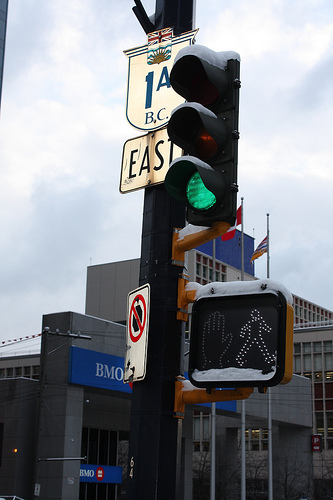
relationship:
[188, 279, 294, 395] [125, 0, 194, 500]
cross sign on light post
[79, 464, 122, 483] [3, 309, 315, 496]
blue sign for a bank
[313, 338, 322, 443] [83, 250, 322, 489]
windows on a building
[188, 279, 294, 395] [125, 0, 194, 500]
cross sign on a light post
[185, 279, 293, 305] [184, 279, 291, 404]
snow on a sign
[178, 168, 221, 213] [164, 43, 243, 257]
light on sign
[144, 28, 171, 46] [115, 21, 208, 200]
flag on sign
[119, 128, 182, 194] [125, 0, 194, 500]
direction sign on light post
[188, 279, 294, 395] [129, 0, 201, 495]
cross sign on pole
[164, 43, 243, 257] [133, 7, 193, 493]
sign on pole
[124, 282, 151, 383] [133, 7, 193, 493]
sign on pole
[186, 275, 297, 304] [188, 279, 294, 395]
snow on cross sign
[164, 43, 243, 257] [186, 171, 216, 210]
sign with light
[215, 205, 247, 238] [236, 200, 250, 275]
flag on pole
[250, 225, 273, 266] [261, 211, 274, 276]
flag on pole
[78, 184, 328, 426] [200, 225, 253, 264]
building with accent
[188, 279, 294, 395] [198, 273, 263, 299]
cross sign with snow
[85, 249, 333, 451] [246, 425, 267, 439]
building with lights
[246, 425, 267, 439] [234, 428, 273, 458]
lights visible through windows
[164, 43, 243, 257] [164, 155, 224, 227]
sign showing light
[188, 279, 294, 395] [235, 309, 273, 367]
cross sign showing a image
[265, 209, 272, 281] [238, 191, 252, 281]
pole on a pole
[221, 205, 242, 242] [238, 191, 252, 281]
flag on a pole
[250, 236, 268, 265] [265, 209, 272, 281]
flag on a pole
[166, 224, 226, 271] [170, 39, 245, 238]
arm of traffic light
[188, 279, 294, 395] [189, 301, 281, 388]
cross sign on cross sign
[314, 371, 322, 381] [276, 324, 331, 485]
window on building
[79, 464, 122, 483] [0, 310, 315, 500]
blue sign on bank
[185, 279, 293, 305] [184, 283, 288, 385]
snow on bottom of sign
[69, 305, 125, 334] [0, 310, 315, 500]
snow on bank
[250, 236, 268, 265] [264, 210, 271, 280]
flag flying on pole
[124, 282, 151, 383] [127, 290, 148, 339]
sign with a cross out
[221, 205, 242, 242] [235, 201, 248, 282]
flag flying on pole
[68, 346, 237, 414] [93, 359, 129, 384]
business sign with letters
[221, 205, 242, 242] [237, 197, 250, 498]
flag on pole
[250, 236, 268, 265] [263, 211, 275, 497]
flag on pole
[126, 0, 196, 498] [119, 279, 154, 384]
light post with sign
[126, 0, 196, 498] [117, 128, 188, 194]
light post with sign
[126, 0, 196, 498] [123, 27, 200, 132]
light post with roadway sign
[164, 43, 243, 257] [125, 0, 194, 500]
sign on light post